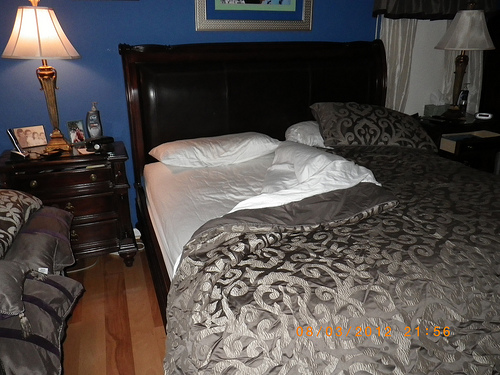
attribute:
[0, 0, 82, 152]
light — on, blue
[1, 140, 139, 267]
table — wood, brown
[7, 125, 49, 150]
picture — black, white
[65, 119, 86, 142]
picture — colored, small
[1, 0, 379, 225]
wall — blue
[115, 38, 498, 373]
bed — unmade, brown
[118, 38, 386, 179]
headboard — brown, black, wooden, dark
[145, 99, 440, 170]
pillows — white, gray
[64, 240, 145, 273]
wire — gray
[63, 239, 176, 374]
floor — wood, brown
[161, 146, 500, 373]
linens — gray, silver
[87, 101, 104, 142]
bottle — lotion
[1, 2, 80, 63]
shade — white, lit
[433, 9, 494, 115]
light — off, not on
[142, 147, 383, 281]
sheet — white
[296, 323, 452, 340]
stamp — time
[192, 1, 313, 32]
frame — silver